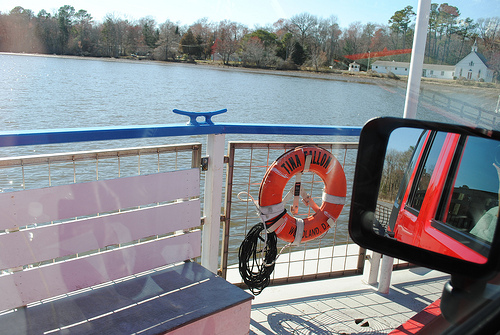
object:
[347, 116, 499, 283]
mirror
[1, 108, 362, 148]
rail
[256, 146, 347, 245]
lifesaver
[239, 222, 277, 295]
rope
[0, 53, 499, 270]
water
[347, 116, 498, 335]
car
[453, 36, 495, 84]
church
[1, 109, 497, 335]
ferry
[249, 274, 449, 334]
shadow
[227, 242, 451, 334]
floor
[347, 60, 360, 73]
gazebo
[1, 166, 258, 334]
fence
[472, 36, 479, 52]
steeple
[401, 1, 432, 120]
pole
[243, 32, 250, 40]
leaves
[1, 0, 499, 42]
sky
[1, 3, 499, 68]
trees